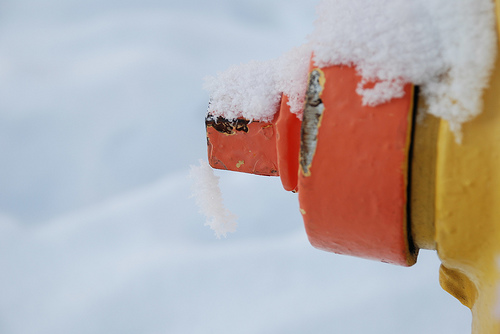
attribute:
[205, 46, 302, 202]
screw — orange 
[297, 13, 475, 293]
fitting — orange 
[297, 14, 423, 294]
fitting — orange 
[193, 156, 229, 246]
snow — flakes , interconnected 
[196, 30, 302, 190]
cap — red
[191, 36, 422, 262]
cap — red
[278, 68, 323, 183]
chips — paint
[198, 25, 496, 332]
hydrant — worn , peeled , painted , flakes , fire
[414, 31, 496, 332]
body — yellow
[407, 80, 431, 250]
threads — metal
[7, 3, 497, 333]
snow — thick, white, loose 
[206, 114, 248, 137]
rust — black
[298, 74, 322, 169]
rust — white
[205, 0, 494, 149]
snow — white , fluffy, wet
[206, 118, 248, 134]
hole — black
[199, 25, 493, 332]
fire hydrant — pictured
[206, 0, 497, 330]
fire hydrant — orange, yellow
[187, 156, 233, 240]
snow — dangling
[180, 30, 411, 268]
cap — orange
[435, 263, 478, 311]
corner — dirty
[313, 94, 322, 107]
speckle — brown